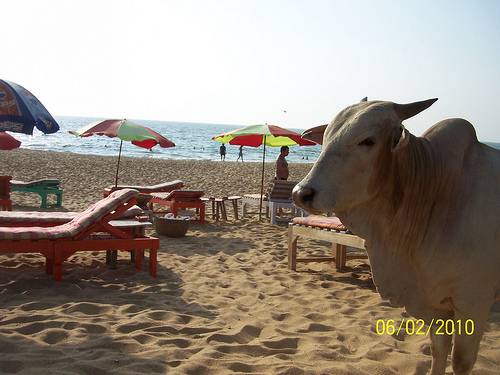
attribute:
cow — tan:
[279, 56, 469, 346]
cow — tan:
[293, 96, 476, 337]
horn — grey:
[397, 97, 437, 119]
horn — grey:
[298, 120, 328, 144]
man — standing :
[273, 142, 295, 182]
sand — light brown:
[2, 145, 497, 373]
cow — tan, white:
[290, 93, 499, 374]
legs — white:
[428, 323, 484, 373]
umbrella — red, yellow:
[213, 113, 311, 161]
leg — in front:
[421, 311, 452, 372]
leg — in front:
[452, 311, 485, 371]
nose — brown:
[290, 172, 326, 226]